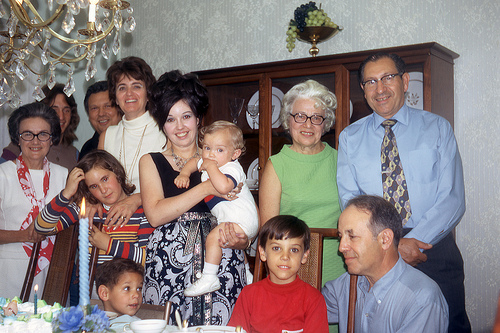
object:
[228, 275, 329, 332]
red shirt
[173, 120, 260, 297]
baby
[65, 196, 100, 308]
candle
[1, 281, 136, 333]
cake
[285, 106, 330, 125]
glasses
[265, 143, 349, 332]
green dress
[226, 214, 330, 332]
boy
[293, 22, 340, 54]
bowl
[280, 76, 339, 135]
grey hair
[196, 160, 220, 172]
hand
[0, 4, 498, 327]
wall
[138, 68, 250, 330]
woman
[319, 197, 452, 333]
man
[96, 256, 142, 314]
boy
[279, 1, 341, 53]
grapes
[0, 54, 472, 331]
people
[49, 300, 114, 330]
flowers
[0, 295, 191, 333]
table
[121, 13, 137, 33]
crystal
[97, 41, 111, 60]
crystal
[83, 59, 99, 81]
crystal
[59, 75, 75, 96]
crystal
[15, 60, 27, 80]
crystal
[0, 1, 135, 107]
chandelier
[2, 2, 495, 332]
wallpaper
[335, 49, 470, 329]
man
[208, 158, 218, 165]
mouth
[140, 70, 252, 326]
mother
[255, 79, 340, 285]
woman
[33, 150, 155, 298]
girl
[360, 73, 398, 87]
glasses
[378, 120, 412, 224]
necktie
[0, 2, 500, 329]
dining room